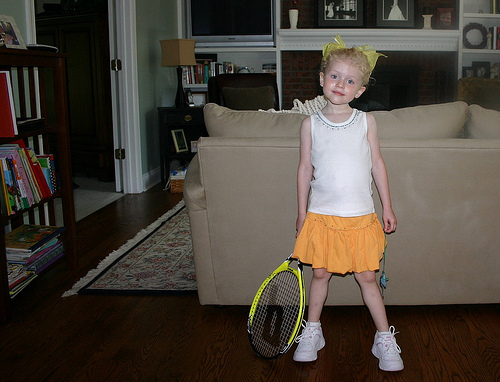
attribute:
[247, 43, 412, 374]
girl holding racket — very cute little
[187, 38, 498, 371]
girl is behind sofa — tan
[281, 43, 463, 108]
fireplace is brick — stone 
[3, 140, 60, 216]
books are upright — nother row 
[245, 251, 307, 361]
racket is small —  child sized tennis 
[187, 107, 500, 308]
couch is big — big beige 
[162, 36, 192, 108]
lamp is brown — brown ,  corner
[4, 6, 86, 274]
bookshelf — Wooden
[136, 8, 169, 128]
wall — against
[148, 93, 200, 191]
table — end 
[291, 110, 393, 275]
outfit — tennis 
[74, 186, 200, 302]
rug — persian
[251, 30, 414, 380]
girl — young 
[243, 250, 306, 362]
racket — tennis 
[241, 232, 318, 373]
racket — tennis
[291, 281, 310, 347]
rim — yellow, black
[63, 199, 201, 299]
rug — area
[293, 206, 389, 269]
skirt — yellow-orange 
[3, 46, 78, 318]
shelving unit — dark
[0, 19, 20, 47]
photograph — framed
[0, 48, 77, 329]
shelf — wood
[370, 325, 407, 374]
shoe — white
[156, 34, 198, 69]
lamp shade — tan, square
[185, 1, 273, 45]
television — silver, large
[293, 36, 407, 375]
girl — little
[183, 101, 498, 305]
couch — tan, beige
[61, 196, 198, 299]
area rug — frayed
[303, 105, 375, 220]
tank top — white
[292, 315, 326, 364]
shoe — white